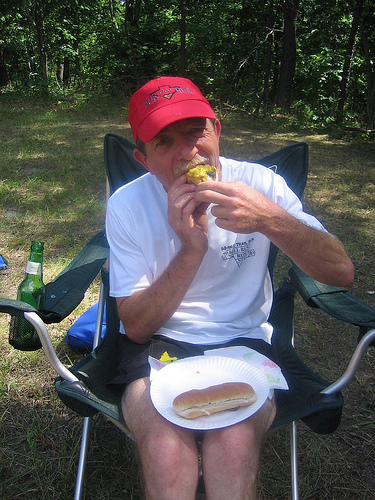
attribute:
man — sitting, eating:
[103, 75, 353, 500]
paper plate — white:
[148, 355, 270, 432]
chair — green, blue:
[3, 135, 374, 439]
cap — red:
[123, 75, 216, 138]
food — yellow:
[183, 164, 218, 188]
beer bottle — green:
[13, 240, 49, 351]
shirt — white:
[100, 157, 320, 350]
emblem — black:
[219, 236, 261, 268]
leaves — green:
[222, 23, 279, 94]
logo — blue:
[136, 84, 192, 106]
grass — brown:
[319, 147, 364, 176]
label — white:
[22, 258, 46, 280]